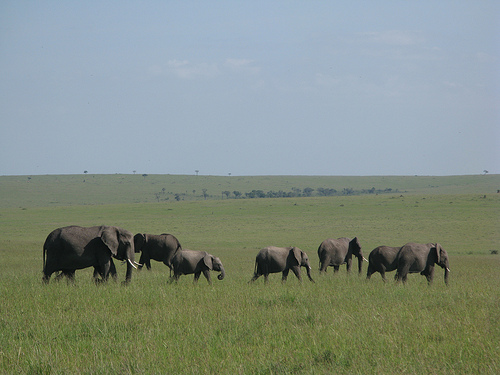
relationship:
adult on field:
[42, 222, 144, 284] [0, 173, 498, 373]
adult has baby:
[42, 222, 144, 284] [391, 239, 452, 289]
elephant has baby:
[133, 230, 182, 276] [364, 242, 402, 281]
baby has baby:
[244, 244, 315, 287] [317, 232, 367, 277]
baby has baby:
[317, 237, 366, 276] [244, 244, 315, 287]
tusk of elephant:
[124, 256, 141, 270] [36, 215, 138, 281]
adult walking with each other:
[42, 222, 144, 284] [29, 212, 444, 296]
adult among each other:
[42, 222, 144, 284] [29, 212, 444, 296]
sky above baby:
[12, 24, 457, 171] [391, 239, 452, 289]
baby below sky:
[391, 239, 452, 289] [12, 24, 457, 171]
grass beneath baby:
[2, 175, 499, 372] [391, 239, 452, 289]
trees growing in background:
[164, 180, 415, 207] [11, 115, 491, 227]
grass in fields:
[2, 175, 499, 372] [2, 177, 494, 369]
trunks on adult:
[122, 253, 138, 277] [42, 222, 144, 284]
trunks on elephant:
[217, 266, 225, 278] [250, 241, 312, 279]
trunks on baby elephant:
[302, 263, 317, 285] [168, 249, 225, 282]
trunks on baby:
[440, 259, 454, 286] [391, 239, 452, 289]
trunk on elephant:
[208, 261, 228, 284] [168, 252, 228, 281]